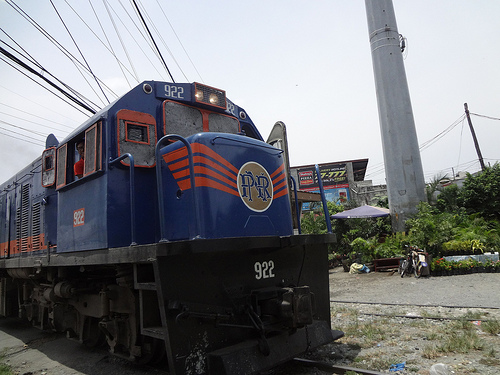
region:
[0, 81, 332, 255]
The train is blue and orange.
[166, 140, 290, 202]
The train front has orange stripes.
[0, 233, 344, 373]
The bottom part of the train is black.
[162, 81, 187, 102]
The train number is 922.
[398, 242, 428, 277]
A bicycle is propped up.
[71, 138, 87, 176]
Someone is inside the train.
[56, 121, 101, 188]
The windows are open.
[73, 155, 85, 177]
The man wears an orange shirt.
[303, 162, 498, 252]
Green plants are on the side of train.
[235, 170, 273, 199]
The letters PNR appear in the train company logo.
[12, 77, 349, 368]
A blue, red and black train engine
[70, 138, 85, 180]
window of train engine with man in red shirt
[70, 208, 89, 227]
number 922 in white and red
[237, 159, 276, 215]
railroad insignia reading PNR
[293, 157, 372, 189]
large advertising billboard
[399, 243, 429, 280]
bicycle parked by bushes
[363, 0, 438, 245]
a tall concrete pole surrounded by bushes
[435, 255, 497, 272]
low vegetation with reddish orange flowers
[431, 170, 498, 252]
green leafy trees and bushes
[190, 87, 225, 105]
train engine's headlights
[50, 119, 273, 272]
red and blue train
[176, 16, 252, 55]
white clouds in blue sky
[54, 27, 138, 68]
white clouds in blue sky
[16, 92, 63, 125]
white clouds in blue sky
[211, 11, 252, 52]
white clouds in blue sky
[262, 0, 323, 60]
white clouds in blue sky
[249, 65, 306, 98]
white clouds in blue sky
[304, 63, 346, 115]
white clouds in blue sky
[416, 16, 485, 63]
white clouds in blue sky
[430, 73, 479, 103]
white clouds in blue sky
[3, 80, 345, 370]
blue and red train on tracks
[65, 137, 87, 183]
train engineer is looking out the window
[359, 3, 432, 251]
large metal silver electric pole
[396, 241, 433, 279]
empty bicycle parked on the sand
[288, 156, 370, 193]
billboard advertisment behind the train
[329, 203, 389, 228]
blue umbrella is open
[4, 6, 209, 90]
several electrical wires over train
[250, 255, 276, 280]
922 painted on the front of the train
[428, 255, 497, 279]
row of potted flowers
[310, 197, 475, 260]
line of bushes next to the tracks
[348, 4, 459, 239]
pole made of metal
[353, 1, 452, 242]
the pole is gray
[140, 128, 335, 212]
red lines on the train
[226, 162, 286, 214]
gold and white logo on train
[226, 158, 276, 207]
blue letters on train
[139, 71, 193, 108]
white numbers on train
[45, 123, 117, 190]
window on train is open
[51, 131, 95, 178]
man in the window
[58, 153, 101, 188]
man's shirt is red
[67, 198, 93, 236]
red logo on train